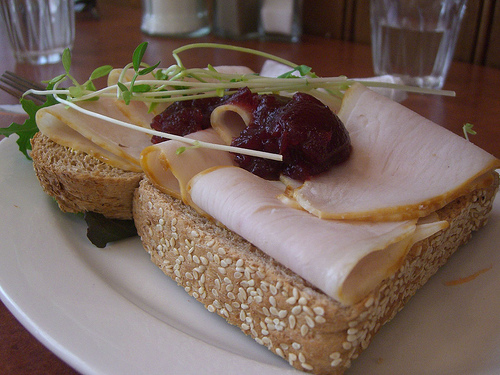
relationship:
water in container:
[372, 19, 450, 90] [369, 0, 467, 90]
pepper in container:
[216, 1, 258, 35] [201, 10, 302, 40]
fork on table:
[1, 69, 173, 112] [3, 16, 499, 371]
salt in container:
[262, 4, 292, 34] [256, 6, 303, 43]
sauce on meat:
[149, 88, 348, 184] [62, 38, 497, 294]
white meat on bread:
[33, 83, 495, 303] [29, 76, 498, 373]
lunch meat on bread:
[35, 60, 500, 306] [134, 164, 498, 371]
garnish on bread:
[8, 39, 456, 166] [29, 65, 498, 373]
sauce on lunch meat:
[149, 86, 353, 181] [35, 60, 500, 306]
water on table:
[372, 18, 445, 78] [200, 18, 498, 178]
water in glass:
[372, 18, 445, 78] [360, 0, 462, 102]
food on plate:
[22, 44, 497, 373] [0, 88, 497, 373]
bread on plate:
[29, 65, 498, 373] [16, 245, 178, 364]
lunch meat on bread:
[35, 60, 500, 306] [19, 112, 354, 373]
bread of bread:
[29, 76, 498, 373] [29, 65, 498, 373]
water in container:
[372, 18, 445, 78] [369, 0, 467, 90]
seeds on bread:
[141, 187, 493, 372] [134, 164, 498, 371]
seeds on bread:
[29, 164, 49, 180] [26, 129, 134, 219]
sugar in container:
[146, 2, 204, 34] [137, 0, 212, 40]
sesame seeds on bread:
[142, 206, 238, 295] [29, 65, 498, 373]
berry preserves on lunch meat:
[232, 80, 368, 189] [35, 60, 500, 306]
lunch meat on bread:
[27, 57, 499, 305] [29, 65, 498, 373]